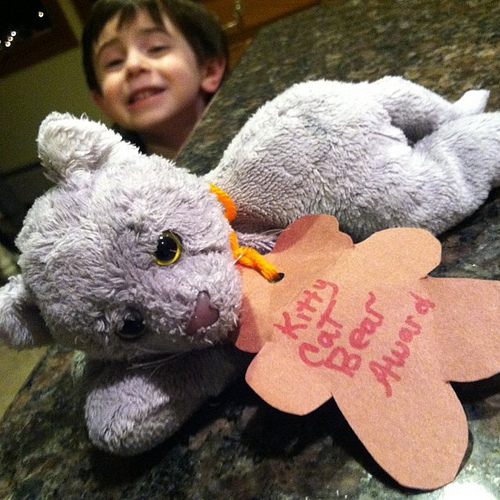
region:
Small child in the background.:
[76, 7, 242, 132]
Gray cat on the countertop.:
[1, 70, 499, 456]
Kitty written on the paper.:
[271, 263, 334, 345]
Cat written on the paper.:
[297, 302, 343, 371]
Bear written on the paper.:
[323, 286, 387, 383]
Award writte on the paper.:
[366, 290, 435, 400]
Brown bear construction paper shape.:
[231, 208, 498, 492]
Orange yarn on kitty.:
[201, 183, 278, 280]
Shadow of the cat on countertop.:
[31, 349, 497, 491]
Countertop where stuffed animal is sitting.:
[6, 5, 499, 497]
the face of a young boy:
[81, 0, 228, 135]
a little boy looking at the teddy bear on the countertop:
[80, 0, 232, 132]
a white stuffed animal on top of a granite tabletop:
[1, 73, 498, 457]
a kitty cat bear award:
[206, 177, 498, 490]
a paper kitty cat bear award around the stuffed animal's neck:
[207, 178, 498, 490]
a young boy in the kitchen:
[1, 1, 498, 142]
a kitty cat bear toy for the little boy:
[1, 73, 498, 457]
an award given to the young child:
[2, 73, 498, 498]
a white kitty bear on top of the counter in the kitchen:
[3, 74, 497, 499]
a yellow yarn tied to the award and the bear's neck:
[210, 180, 279, 280]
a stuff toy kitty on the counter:
[3, 68, 494, 448]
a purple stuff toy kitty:
[3, 70, 498, 426]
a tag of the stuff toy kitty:
[253, 216, 480, 492]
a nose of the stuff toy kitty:
[179, 285, 223, 343]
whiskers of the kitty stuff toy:
[122, 359, 186, 381]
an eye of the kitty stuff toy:
[146, 224, 187, 271]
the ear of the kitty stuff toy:
[23, 106, 130, 193]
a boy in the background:
[62, 1, 222, 119]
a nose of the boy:
[121, 46, 153, 79]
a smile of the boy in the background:
[121, 81, 168, 109]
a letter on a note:
[269, 310, 306, 338]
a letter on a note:
[297, 346, 319, 371]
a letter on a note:
[361, 356, 401, 401]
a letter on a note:
[386, 346, 415, 363]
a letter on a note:
[397, 300, 420, 335]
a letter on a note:
[411, 288, 441, 316]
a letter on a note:
[289, 293, 319, 311]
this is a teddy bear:
[1, 79, 492, 460]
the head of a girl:
[72, 17, 232, 149]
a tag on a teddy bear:
[249, 214, 497, 493]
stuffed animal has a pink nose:
[186, 289, 218, 334]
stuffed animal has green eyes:
[115, 230, 180, 341]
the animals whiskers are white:
[132, 347, 192, 377]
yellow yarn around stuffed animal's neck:
[220, 194, 275, 280]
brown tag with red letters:
[279, 278, 439, 390]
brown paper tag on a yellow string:
[242, 212, 494, 478]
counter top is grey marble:
[214, 444, 320, 487]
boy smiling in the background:
[80, 2, 229, 129]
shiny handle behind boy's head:
[214, 2, 256, 35]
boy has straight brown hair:
[86, 1, 213, 32]